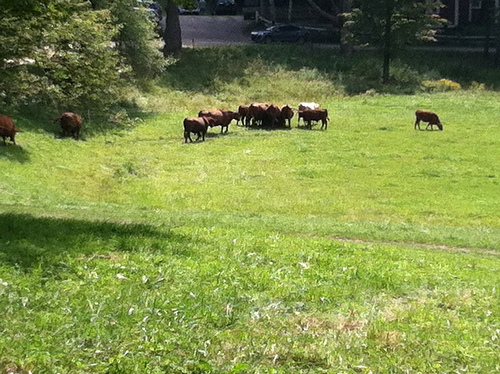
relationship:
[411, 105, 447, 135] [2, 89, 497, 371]
cow grazing on grass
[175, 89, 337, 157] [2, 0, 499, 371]
cow grazing on field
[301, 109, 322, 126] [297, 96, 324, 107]
cow next to cow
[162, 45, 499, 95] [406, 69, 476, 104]
weeds with flowers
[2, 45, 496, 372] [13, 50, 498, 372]
grass in pasture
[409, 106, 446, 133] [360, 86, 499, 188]
cow on grass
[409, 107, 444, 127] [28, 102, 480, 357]
cow in field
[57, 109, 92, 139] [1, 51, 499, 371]
cow in field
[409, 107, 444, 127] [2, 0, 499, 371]
cow in field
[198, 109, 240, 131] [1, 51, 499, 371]
cow in field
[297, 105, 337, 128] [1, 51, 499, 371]
cow in field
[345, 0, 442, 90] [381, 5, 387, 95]
tree has trunk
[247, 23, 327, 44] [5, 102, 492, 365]
car parked behind field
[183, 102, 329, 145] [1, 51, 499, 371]
cows in field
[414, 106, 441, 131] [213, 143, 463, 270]
cow in field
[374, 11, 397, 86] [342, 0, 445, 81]
trunk of tree